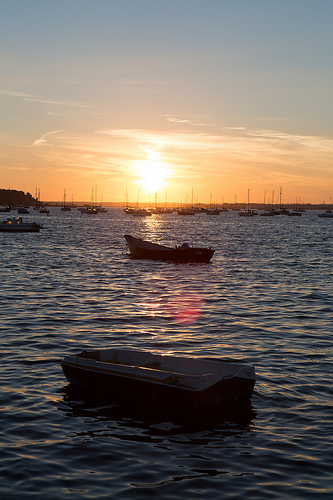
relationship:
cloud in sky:
[93, 129, 332, 170] [0, 0, 332, 205]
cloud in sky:
[165, 116, 205, 126] [0, 0, 332, 205]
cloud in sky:
[219, 125, 246, 134] [0, 0, 332, 205]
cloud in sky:
[30, 129, 63, 147] [0, 0, 332, 205]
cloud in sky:
[23, 97, 93, 108] [0, 0, 332, 205]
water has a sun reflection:
[0, 205, 332, 499] [141, 208, 164, 232]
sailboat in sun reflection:
[132, 187, 153, 216] [141, 208, 164, 232]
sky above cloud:
[0, 0, 332, 205] [23, 97, 93, 108]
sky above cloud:
[0, 0, 332, 205] [30, 129, 63, 147]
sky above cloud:
[0, 0, 332, 205] [165, 116, 205, 126]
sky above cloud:
[0, 0, 332, 205] [93, 129, 332, 170]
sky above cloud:
[0, 0, 332, 205] [219, 125, 246, 134]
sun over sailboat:
[124, 151, 177, 195] [60, 187, 72, 212]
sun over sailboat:
[124, 151, 177, 195] [124, 187, 136, 214]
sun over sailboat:
[124, 151, 177, 195] [132, 187, 153, 216]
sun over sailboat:
[124, 151, 177, 195] [176, 192, 194, 215]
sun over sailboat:
[124, 151, 177, 195] [236, 189, 258, 217]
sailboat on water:
[60, 187, 72, 212] [0, 205, 332, 499]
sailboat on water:
[124, 187, 136, 214] [0, 205, 332, 499]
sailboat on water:
[132, 187, 153, 216] [0, 205, 332, 499]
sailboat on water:
[176, 192, 194, 215] [0, 205, 332, 499]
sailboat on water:
[236, 189, 258, 217] [0, 205, 332, 499]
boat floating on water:
[60, 348, 257, 411] [0, 205, 332, 499]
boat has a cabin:
[0, 216, 44, 232] [4, 216, 23, 224]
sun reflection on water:
[141, 208, 164, 232] [0, 205, 332, 499]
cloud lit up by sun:
[93, 129, 332, 170] [124, 151, 177, 195]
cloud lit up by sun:
[30, 129, 63, 147] [124, 151, 177, 195]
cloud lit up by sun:
[23, 97, 93, 108] [124, 151, 177, 195]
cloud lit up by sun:
[219, 125, 246, 134] [124, 151, 177, 195]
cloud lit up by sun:
[165, 116, 205, 126] [124, 151, 177, 195]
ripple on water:
[132, 473, 229, 492] [0, 205, 332, 499]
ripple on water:
[4, 451, 81, 474] [0, 205, 332, 499]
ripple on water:
[8, 423, 52, 435] [0, 205, 332, 499]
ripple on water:
[264, 441, 311, 451] [0, 205, 332, 499]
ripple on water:
[287, 415, 315, 424] [0, 205, 332, 499]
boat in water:
[60, 348, 257, 411] [0, 205, 332, 499]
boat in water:
[124, 234, 214, 263] [0, 205, 332, 499]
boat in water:
[0, 216, 44, 232] [0, 205, 332, 499]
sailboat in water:
[60, 187, 72, 212] [0, 205, 332, 499]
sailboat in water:
[124, 187, 136, 214] [0, 205, 332, 499]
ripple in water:
[8, 423, 52, 435] [0, 205, 332, 499]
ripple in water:
[4, 451, 81, 474] [0, 205, 332, 499]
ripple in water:
[132, 473, 229, 492] [0, 205, 332, 499]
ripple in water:
[264, 441, 311, 451] [0, 205, 332, 499]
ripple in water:
[287, 415, 315, 424] [0, 205, 332, 499]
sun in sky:
[124, 151, 177, 195] [0, 0, 332, 205]